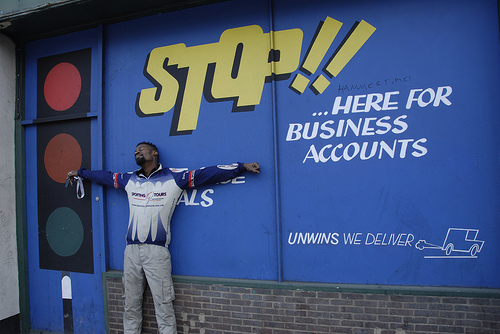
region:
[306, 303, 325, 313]
brick on the wall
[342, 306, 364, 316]
brick on the wall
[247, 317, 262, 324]
brick on the wall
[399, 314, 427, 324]
brick on the wall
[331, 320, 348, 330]
brick on the wall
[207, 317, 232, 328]
brick on the wall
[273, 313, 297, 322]
brick on the wall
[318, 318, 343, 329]
brick on the wall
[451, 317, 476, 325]
brick on the wall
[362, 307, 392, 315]
brick on the wall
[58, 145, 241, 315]
Man leaning against the wall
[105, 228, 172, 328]
Man wearing gray pants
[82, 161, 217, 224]
man wearing a blue and gray shirt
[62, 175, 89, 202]
Man holding on to key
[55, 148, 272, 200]
man with his arms out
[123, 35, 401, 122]
the word stop painted on the wall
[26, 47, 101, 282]
traffic light painted on the wall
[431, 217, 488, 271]
truck painted on the wall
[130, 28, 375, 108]
Yellow word stop painted on wall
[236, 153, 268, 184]
man hand against the wall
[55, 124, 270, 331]
a man standing against a wall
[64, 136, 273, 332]
a man with his arms outstretched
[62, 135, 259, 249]
a man wearing a blue and white jacket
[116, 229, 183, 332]
a man wearing gray pants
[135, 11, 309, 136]
a sign that says Stop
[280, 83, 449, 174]
a sign that says Here For Business Accounts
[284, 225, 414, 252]
a sign that says Unwins We Deliver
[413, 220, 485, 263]
a stick drawing of a truck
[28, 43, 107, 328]
A sign with a painted stoplight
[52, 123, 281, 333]
a man standing in front of a sign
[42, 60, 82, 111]
circle is bright red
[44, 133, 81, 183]
cirlce is dark red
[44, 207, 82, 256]
circle is dark blue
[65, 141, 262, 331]
man against wall with arms stretched out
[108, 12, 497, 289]
blue sign behind man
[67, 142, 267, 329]
man wearing white shirt with blue sleeves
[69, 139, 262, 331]
man wearing white pants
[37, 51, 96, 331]
traffic light painted on wall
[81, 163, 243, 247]
shirt is white with blue sleeves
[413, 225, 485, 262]
painting of white truck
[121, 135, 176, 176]
the head of a man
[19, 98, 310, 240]
a man wearing a jacket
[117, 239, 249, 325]
a man wearing pants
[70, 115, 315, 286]
a man leaning against a building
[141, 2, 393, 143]
the word stop on a building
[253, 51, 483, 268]
words on the side of a building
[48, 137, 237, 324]
a man standing with his arms out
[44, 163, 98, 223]
the hand of a man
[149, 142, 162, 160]
the ear of a man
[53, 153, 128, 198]
a man holding keys in his hand